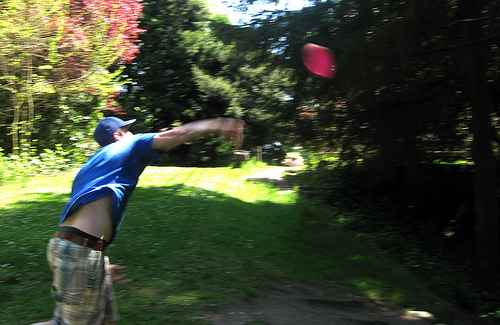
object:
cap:
[93, 116, 137, 146]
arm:
[137, 117, 245, 150]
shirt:
[57, 132, 168, 245]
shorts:
[27, 226, 117, 325]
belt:
[54, 231, 108, 252]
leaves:
[114, 1, 136, 66]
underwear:
[57, 226, 111, 245]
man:
[26, 115, 247, 324]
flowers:
[70, 130, 95, 153]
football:
[302, 43, 340, 79]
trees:
[176, 8, 300, 132]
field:
[103, 164, 461, 325]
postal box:
[232, 149, 251, 161]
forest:
[239, 2, 500, 280]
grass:
[0, 160, 86, 325]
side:
[89, 155, 133, 242]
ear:
[113, 132, 124, 141]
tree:
[121, 0, 212, 127]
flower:
[122, 12, 137, 22]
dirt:
[206, 284, 440, 325]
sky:
[203, 0, 323, 30]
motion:
[301, 43, 336, 79]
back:
[58, 198, 104, 234]